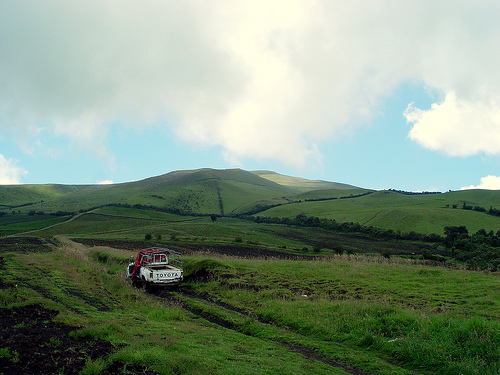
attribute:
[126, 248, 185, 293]
truck — white, junk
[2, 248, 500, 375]
field — green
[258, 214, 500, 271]
trees — green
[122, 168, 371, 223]
mountain — green, small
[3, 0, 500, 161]
clouds — white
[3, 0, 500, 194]
sky — blue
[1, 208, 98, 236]
road — dirt